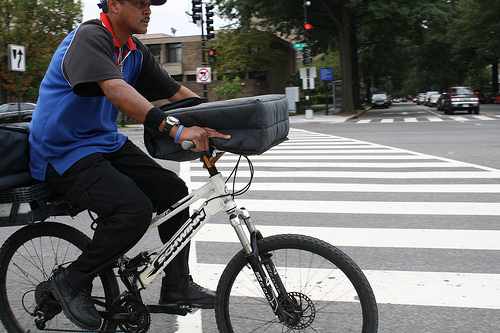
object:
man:
[27, 0, 234, 332]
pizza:
[144, 93, 290, 162]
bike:
[1, 139, 377, 333]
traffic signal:
[192, 0, 202, 24]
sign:
[8, 45, 25, 74]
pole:
[16, 71, 23, 126]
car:
[442, 86, 479, 116]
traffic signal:
[303, 22, 312, 42]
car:
[437, 93, 447, 110]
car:
[431, 93, 441, 108]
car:
[416, 94, 426, 105]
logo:
[147, 206, 208, 279]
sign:
[195, 65, 214, 83]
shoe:
[44, 268, 103, 331]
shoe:
[158, 277, 215, 310]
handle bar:
[181, 141, 195, 154]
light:
[305, 24, 312, 32]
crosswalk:
[173, 122, 499, 333]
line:
[191, 183, 500, 193]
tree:
[208, 0, 461, 114]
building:
[115, 33, 296, 114]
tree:
[206, 28, 293, 97]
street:
[0, 91, 500, 332]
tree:
[442, 0, 499, 103]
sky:
[0, 1, 240, 31]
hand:
[175, 125, 231, 152]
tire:
[215, 234, 379, 333]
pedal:
[146, 305, 201, 315]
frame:
[112, 171, 302, 333]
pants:
[45, 138, 188, 292]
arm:
[78, 34, 230, 152]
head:
[97, 0, 152, 35]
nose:
[142, 5, 152, 15]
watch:
[160, 116, 177, 140]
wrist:
[160, 119, 185, 145]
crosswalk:
[347, 110, 500, 124]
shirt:
[24, 13, 180, 181]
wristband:
[175, 125, 182, 147]